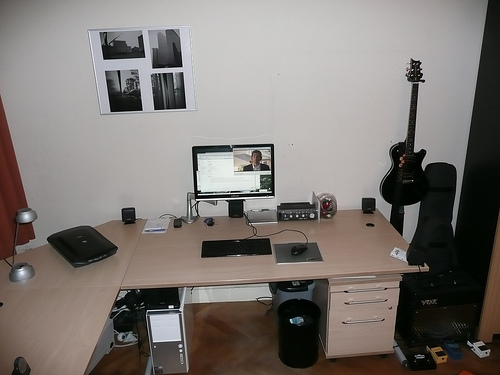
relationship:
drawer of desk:
[326, 292, 397, 360] [0, 210, 432, 375]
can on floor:
[262, 290, 329, 373] [206, 306, 260, 360]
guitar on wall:
[382, 53, 440, 214] [2, 2, 498, 306]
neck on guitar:
[405, 82, 422, 145] [377, 57, 430, 207]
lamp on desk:
[10, 207, 53, 277] [2, 200, 420, 357]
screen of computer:
[189, 146, 276, 199] [188, 143, 277, 223]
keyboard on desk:
[199, 238, 271, 257] [0, 210, 432, 375]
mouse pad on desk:
[273, 239, 294, 265] [311, 222, 373, 297]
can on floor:
[274, 297, 323, 369] [95, 303, 495, 374]